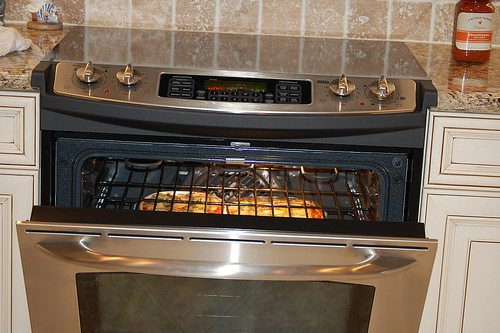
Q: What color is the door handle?
A: Silver.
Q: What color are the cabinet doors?
A: Tan.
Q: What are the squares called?
A: Tiles.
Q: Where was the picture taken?
A: In a kitchen.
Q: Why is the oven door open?
A: To view the food.